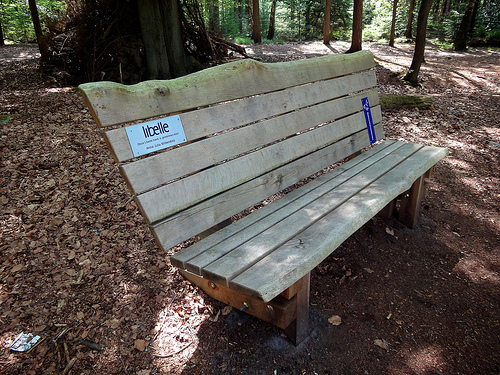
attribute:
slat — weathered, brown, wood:
[100, 59, 448, 323]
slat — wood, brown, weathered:
[146, 115, 334, 255]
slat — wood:
[72, 44, 381, 129]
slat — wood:
[99, 65, 391, 166]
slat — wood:
[112, 98, 392, 194]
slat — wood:
[122, 100, 398, 221]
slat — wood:
[150, 138, 448, 259]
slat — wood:
[241, 140, 453, 310]